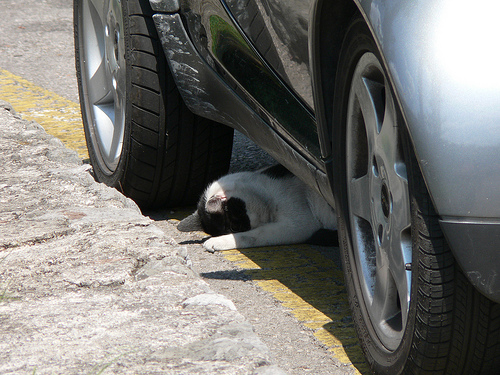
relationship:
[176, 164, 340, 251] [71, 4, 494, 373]
adult cat under car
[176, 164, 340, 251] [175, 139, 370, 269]
adult cat under car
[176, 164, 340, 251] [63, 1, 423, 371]
adult cat under car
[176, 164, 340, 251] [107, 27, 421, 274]
adult cat under car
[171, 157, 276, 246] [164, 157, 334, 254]
head of cat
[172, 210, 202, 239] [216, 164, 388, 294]
ear of cat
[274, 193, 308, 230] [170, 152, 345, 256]
white on cat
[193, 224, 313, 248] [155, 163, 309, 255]
leg on cat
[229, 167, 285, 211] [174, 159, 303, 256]
neck on cat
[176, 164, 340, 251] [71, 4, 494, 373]
adult cat napping under car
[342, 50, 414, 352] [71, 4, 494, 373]
rim on car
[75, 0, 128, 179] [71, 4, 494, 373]
rim on car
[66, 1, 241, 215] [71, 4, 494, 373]
back tire on a car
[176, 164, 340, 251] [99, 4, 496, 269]
adult cat under car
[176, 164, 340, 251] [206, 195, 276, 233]
adult cat has face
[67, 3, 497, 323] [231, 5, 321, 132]
car reflects seat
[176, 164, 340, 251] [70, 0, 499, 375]
adult cat napping under car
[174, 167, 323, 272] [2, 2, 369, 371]
adult cat sleeping on road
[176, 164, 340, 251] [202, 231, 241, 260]
adult cat with paw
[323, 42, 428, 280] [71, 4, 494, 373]
tire on car